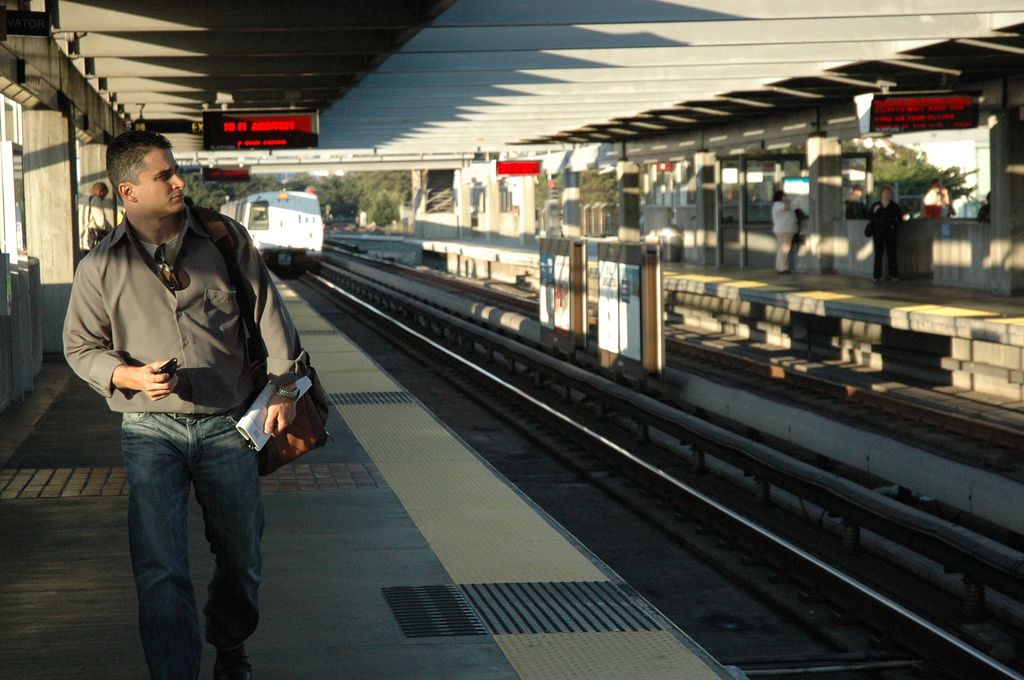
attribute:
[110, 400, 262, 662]
jeans — blue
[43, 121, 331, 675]
man —  holding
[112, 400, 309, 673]
jeans — blue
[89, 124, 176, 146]
hair — dark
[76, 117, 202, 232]
head — turned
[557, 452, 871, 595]
rod — metal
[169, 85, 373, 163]
sign — red, Black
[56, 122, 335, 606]
man — standing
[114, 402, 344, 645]
jeans — blue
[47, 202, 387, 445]
shirt — gray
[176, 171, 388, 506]
bag — brown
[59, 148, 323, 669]
man — carrying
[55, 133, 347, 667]
man — walking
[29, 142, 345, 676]
man — wearing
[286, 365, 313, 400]
watch —  silver